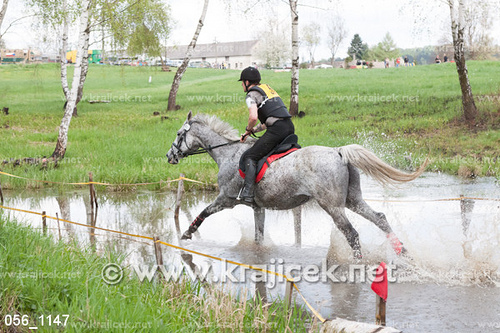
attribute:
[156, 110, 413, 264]
horse — white, movign, wet, grey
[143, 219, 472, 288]
water — splashing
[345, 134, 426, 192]
tail — grey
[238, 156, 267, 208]
boots — black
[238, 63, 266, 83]
hat — black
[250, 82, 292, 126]
vest — black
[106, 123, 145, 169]
grass — green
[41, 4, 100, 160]
tree — here, pine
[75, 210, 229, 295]
barracks — here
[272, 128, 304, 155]
saddle — black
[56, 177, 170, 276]
swamp — here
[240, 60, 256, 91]
helmet — black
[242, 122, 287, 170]
pants — black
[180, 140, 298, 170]
harnest — red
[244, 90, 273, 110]
shirt — grey